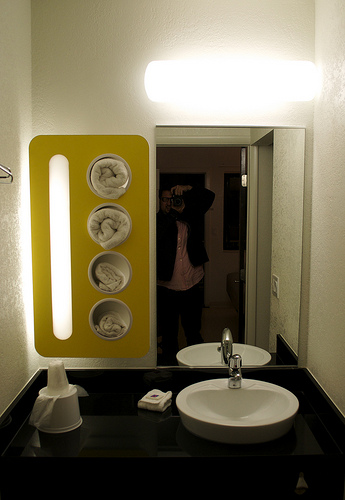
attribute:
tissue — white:
[27, 392, 63, 428]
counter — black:
[0, 361, 341, 498]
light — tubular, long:
[43, 152, 76, 340]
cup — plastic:
[39, 357, 73, 397]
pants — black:
[156, 285, 205, 363]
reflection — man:
[155, 184, 215, 263]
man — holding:
[155, 179, 201, 228]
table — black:
[20, 396, 323, 468]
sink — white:
[176, 374, 301, 443]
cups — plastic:
[30, 362, 81, 442]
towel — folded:
[136, 383, 171, 416]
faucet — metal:
[224, 351, 244, 389]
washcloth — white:
[135, 387, 175, 412]